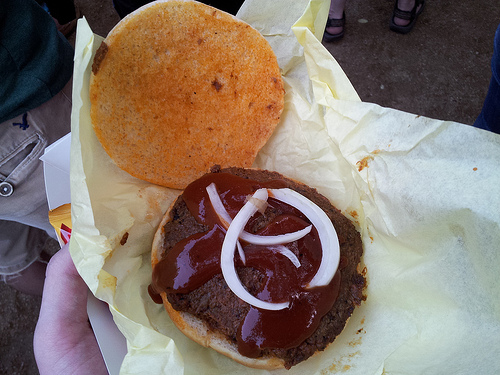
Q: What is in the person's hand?
A: A sandwich.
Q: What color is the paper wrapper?
A: Yellow.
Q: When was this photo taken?
A: During the daytime.